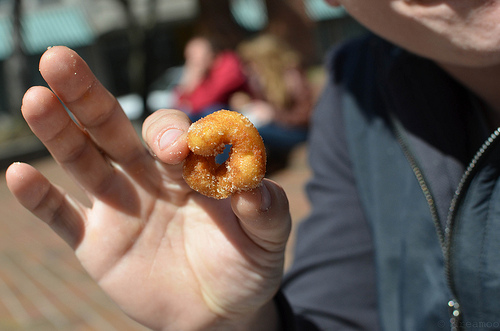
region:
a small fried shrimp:
[182, 113, 267, 191]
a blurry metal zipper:
[445, 297, 461, 323]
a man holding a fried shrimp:
[15, 38, 295, 328]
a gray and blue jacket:
[323, 55, 498, 328]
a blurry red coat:
[181, 52, 243, 112]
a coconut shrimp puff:
[182, 107, 268, 202]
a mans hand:
[13, 47, 284, 326]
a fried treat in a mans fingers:
[151, 103, 297, 242]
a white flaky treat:
[183, 110, 260, 195]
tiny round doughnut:
[183, 113, 268, 198]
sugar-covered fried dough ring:
[186, 111, 265, 199]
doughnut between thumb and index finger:
[146, 108, 288, 245]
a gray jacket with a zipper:
[290, 28, 493, 327]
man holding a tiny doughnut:
[7, 1, 498, 328]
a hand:
[5, 45, 290, 327]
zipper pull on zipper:
[448, 299, 464, 329]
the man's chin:
[386, 17, 498, 71]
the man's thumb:
[231, 184, 289, 247]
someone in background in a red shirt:
[174, 38, 275, 127]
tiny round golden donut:
[182, 107, 274, 207]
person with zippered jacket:
[403, 143, 483, 318]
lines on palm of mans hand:
[129, 180, 215, 280]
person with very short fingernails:
[146, 120, 189, 155]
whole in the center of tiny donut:
[206, 136, 236, 168]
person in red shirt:
[167, 46, 261, 102]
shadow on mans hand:
[65, 148, 155, 258]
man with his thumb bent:
[214, 170, 318, 258]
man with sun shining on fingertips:
[7, 44, 97, 119]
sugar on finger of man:
[47, 45, 104, 95]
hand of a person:
[6, 50, 304, 308]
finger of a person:
[125, 85, 201, 170]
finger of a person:
[28, 31, 90, 101]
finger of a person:
[6, 93, 80, 155]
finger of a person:
[5, 158, 67, 227]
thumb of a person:
[208, 174, 303, 261]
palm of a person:
[100, 185, 223, 315]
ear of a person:
[322, 0, 333, 20]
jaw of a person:
[420, 40, 495, 73]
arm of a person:
[280, 108, 391, 293]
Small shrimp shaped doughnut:
[183, 110, 264, 198]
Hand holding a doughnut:
[6, 44, 290, 329]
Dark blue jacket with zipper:
[284, 30, 499, 330]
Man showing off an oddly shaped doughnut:
[1, 3, 498, 328]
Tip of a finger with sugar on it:
[36, 43, 94, 88]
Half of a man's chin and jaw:
[336, 0, 497, 65]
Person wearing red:
[173, 36, 250, 118]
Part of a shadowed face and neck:
[333, 2, 499, 102]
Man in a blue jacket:
[0, 0, 498, 329]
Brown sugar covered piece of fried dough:
[184, 110, 264, 198]